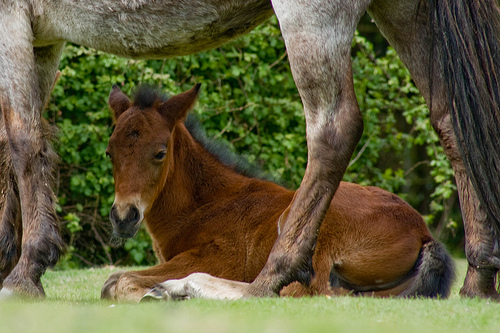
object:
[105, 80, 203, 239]
head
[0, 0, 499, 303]
horse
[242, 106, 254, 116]
leaves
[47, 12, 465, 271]
bushes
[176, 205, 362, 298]
hind leg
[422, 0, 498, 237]
tail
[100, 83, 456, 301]
foal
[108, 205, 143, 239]
muzzle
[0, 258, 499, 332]
grass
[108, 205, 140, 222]
nose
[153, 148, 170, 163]
eye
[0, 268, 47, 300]
hoof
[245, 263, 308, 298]
hoof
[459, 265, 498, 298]
hoof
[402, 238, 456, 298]
tail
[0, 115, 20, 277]
leg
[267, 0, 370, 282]
leg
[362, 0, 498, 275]
leg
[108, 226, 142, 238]
mouth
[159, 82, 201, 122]
ear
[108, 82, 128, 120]
ear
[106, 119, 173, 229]
face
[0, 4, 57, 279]
front leg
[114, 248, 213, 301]
front leg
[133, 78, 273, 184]
main